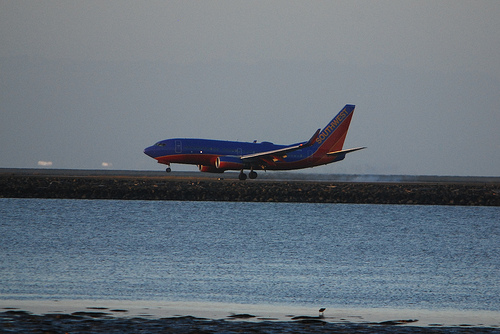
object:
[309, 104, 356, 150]
tail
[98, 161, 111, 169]
object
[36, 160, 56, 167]
object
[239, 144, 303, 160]
white line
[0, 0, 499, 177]
sky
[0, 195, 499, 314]
water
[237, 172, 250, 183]
wheel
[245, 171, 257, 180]
wheel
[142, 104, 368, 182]
airplane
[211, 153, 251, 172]
engine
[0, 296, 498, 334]
shore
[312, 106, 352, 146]
word